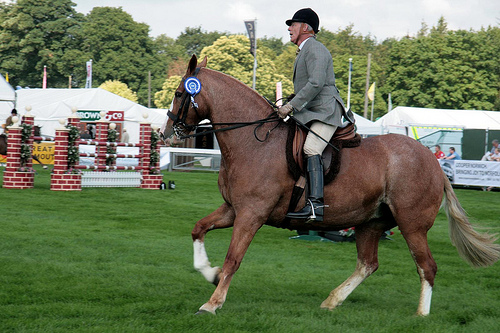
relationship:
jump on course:
[70, 125, 162, 198] [13, 114, 241, 204]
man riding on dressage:
[269, 0, 350, 230] [152, 41, 498, 327]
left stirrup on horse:
[283, 197, 336, 229] [150, 41, 478, 326]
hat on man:
[288, 9, 318, 49] [269, 6, 353, 221]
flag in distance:
[362, 71, 385, 122] [67, 14, 497, 109]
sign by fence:
[452, 155, 498, 198] [177, 136, 222, 176]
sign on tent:
[64, 103, 127, 127] [5, 74, 163, 155]